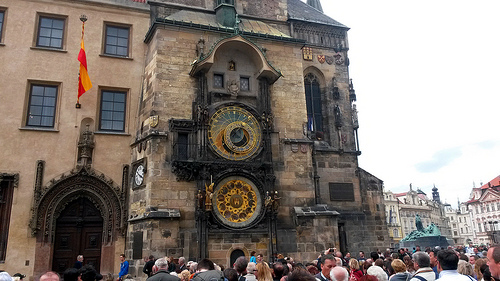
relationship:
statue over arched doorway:
[76, 116, 101, 172] [26, 169, 132, 277]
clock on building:
[199, 106, 270, 169] [116, 11, 400, 279]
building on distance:
[381, 177, 493, 256] [385, 186, 496, 224]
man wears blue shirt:
[115, 250, 136, 276] [116, 256, 140, 277]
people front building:
[405, 244, 436, 280] [5, 4, 390, 277]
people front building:
[327, 260, 357, 280] [5, 4, 390, 277]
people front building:
[248, 259, 274, 280] [5, 4, 390, 277]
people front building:
[317, 252, 341, 280] [5, 4, 390, 277]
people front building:
[151, 252, 185, 279] [5, 4, 390, 277]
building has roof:
[381, 177, 498, 256] [474, 173, 498, 184]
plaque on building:
[324, 179, 356, 209] [5, 4, 390, 277]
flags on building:
[70, 43, 95, 98] [5, 4, 390, 277]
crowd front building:
[1, 242, 498, 279] [5, 4, 390, 277]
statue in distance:
[400, 213, 445, 253] [374, 205, 498, 240]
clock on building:
[128, 160, 149, 186] [5, 4, 390, 277]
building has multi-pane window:
[5, 4, 390, 277] [102, 18, 131, 61]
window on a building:
[98, 83, 126, 136] [5, 4, 390, 277]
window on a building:
[22, 76, 59, 131] [5, 4, 390, 277]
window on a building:
[38, 10, 68, 52] [5, 4, 390, 277]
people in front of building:
[329, 266, 351, 280] [0, 0, 389, 281]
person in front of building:
[392, 248, 410, 276] [0, 0, 389, 281]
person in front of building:
[404, 235, 430, 278] [0, 0, 389, 281]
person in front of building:
[233, 242, 253, 276] [0, 0, 389, 281]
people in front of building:
[151, 252, 185, 280] [0, 0, 389, 281]